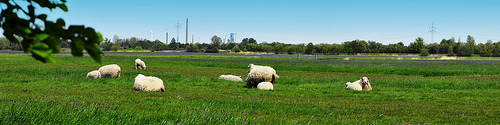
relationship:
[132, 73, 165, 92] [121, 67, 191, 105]
sheep on grass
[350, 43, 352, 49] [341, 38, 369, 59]
leaves on tree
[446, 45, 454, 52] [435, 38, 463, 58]
leaves on tree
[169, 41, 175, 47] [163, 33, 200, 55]
leaves on tree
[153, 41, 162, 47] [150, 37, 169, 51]
leaves on tree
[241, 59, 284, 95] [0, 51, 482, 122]
sheep in grass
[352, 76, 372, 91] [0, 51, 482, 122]
sheep in grass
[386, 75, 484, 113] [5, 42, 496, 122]
grass in field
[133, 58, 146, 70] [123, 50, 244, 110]
sheep eating grass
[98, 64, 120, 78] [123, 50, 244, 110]
sheep eating grass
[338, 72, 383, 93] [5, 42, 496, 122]
sheep in field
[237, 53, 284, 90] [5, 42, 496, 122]
sheep in field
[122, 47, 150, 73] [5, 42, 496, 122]
sheep in field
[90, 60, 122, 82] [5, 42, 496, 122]
sheep in field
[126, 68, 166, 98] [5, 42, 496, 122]
sheep in field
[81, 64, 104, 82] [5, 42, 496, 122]
sheep in field